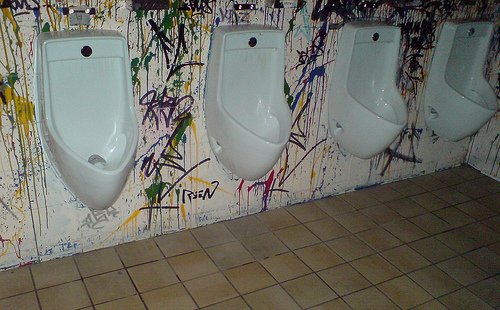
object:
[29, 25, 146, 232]
bathroom urinal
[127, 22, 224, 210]
restroom wall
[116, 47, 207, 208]
scribble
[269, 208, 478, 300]
shapes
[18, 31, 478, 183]
wall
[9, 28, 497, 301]
restroom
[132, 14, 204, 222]
paint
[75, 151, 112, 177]
plastic pad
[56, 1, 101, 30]
sheet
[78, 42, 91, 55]
circle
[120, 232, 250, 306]
tile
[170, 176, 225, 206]
letters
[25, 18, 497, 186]
urinals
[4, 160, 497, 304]
tile floor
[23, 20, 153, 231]
toilet